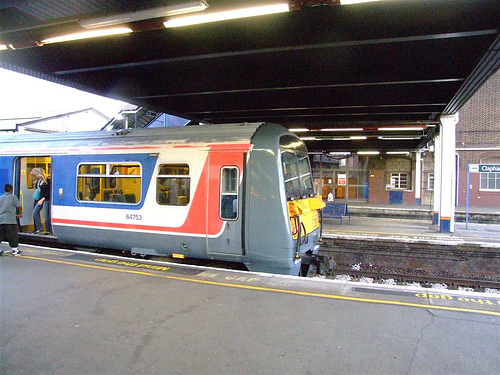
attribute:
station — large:
[0, 1, 497, 373]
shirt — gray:
[3, 191, 20, 225]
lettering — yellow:
[89, 252, 172, 273]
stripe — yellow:
[1, 242, 497, 316]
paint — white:
[61, 118, 298, 262]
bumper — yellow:
[283, 191, 338, 233]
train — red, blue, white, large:
[0, 121, 333, 283]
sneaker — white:
[11, 247, 21, 256]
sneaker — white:
[0, 246, 7, 256]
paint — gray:
[2, 115, 327, 280]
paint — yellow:
[284, 193, 330, 237]